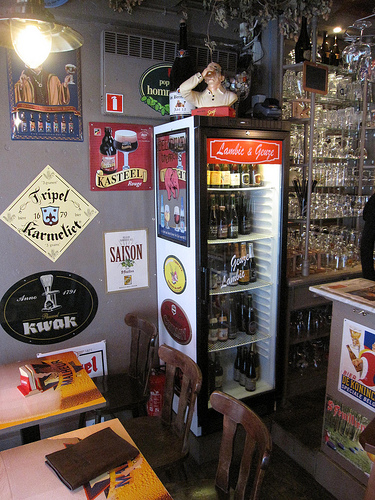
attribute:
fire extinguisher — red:
[146, 363, 167, 413]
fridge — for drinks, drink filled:
[149, 113, 280, 438]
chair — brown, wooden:
[81, 299, 155, 419]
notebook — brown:
[45, 426, 136, 492]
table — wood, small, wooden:
[4, 415, 172, 498]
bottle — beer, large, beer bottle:
[241, 295, 259, 335]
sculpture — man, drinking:
[175, 59, 241, 117]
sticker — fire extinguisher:
[102, 93, 127, 114]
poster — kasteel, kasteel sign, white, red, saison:
[88, 123, 154, 191]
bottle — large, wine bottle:
[161, 18, 198, 115]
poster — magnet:
[152, 127, 195, 249]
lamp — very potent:
[3, 3, 85, 74]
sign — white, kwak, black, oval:
[0, 266, 105, 348]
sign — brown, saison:
[103, 226, 147, 297]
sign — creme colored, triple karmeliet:
[3, 165, 101, 266]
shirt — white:
[179, 73, 235, 107]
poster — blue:
[5, 40, 86, 143]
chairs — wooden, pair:
[117, 343, 279, 499]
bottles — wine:
[210, 192, 259, 239]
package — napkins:
[17, 355, 61, 398]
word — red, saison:
[109, 244, 146, 263]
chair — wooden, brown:
[185, 386, 284, 497]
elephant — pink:
[161, 166, 182, 204]